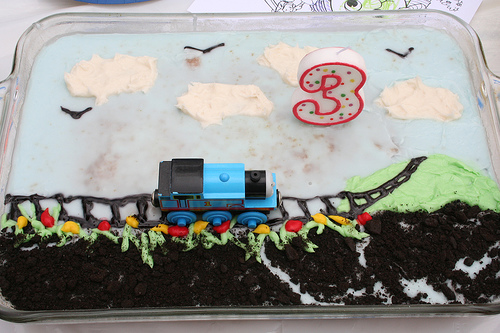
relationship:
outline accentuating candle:
[290, 59, 365, 127] [290, 44, 368, 126]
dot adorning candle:
[330, 69, 335, 75] [290, 44, 368, 126]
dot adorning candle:
[347, 100, 354, 107] [290, 44, 368, 126]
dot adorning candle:
[337, 110, 344, 117] [290, 44, 368, 126]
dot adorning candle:
[345, 69, 352, 77] [290, 44, 368, 126]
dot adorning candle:
[308, 109, 315, 115] [290, 44, 368, 126]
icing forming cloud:
[173, 76, 275, 126] [174, 80, 276, 130]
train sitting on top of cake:
[149, 157, 284, 230] [1, 25, 483, 311]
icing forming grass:
[336, 151, 485, 220] [329, 151, 483, 213]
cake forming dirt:
[1, 40, 500, 313] [0, 201, 482, 309]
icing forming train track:
[4, 154, 427, 228] [2, 154, 428, 227]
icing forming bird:
[59, 105, 94, 120] [60, 104, 95, 121]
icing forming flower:
[12, 206, 372, 235] [38, 206, 56, 226]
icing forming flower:
[12, 206, 372, 235] [57, 218, 81, 235]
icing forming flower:
[12, 206, 372, 235] [95, 218, 111, 231]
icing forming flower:
[12, 206, 372, 235] [166, 225, 189, 238]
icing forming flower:
[12, 206, 372, 235] [252, 223, 271, 234]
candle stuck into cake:
[292, 45, 368, 127] [1, 25, 483, 311]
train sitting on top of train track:
[149, 157, 284, 230] [2, 154, 428, 227]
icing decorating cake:
[60, 220, 80, 239] [1, 25, 483, 311]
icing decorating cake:
[96, 219, 111, 231] [1, 25, 483, 311]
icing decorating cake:
[190, 217, 210, 233] [1, 25, 483, 311]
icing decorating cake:
[126, 214, 232, 238] [1, 25, 483, 311]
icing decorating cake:
[284, 218, 303, 233] [1, 25, 483, 311]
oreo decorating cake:
[420, 290, 429, 298] [1, 25, 483, 311]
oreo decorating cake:
[461, 255, 474, 267] [1, 25, 483, 311]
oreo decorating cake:
[239, 272, 259, 287] [1, 25, 483, 311]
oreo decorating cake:
[18, 233, 43, 248] [1, 25, 483, 311]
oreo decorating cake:
[307, 224, 317, 240] [1, 25, 483, 311]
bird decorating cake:
[58, 104, 92, 119] [1, 25, 483, 311]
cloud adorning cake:
[61, 50, 161, 107] [1, 25, 483, 311]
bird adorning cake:
[183, 40, 226, 55] [1, 25, 483, 311]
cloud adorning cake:
[174, 80, 276, 130] [1, 25, 483, 311]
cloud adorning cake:
[372, 74, 467, 124] [1, 25, 483, 311]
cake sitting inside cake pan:
[1, 25, 483, 311] [4, 10, 500, 322]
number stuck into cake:
[289, 43, 369, 127] [1, 25, 483, 311]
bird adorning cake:
[60, 104, 95, 121] [1, 25, 483, 311]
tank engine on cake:
[152, 155, 281, 231] [1, 25, 483, 311]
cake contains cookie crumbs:
[1, 25, 483, 311] [18, 257, 256, 301]